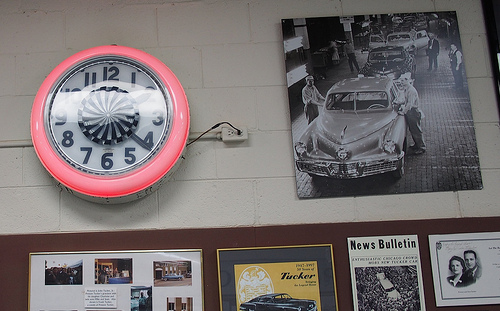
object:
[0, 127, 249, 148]
conduit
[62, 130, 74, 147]
number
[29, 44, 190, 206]
neon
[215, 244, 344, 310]
frame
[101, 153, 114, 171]
number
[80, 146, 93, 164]
number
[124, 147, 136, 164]
number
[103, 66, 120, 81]
number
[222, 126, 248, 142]
outlet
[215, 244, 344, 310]
photo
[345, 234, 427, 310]
photo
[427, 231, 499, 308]
photo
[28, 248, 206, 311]
photo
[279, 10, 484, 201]
photo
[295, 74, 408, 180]
car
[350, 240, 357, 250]
letter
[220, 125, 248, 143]
plug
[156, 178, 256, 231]
block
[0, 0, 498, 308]
wall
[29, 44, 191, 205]
clock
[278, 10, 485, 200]
poster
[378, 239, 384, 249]
letter